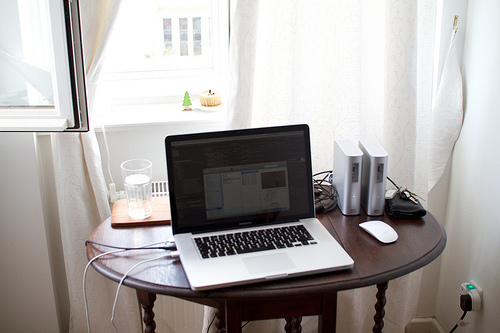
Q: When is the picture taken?
A: Daytime.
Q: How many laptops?
A: One.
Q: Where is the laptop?
A: On the table.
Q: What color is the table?
A: Brown.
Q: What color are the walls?
A: White.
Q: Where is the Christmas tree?
A: On the window sill.